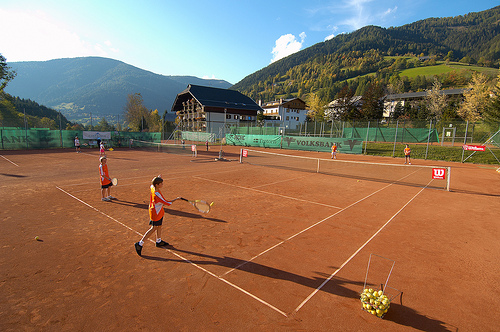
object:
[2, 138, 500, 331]
tennis court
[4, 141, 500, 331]
clay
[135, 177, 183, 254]
tenni player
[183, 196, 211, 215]
racquet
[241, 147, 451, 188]
net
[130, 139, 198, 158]
net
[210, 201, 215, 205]
tennis ball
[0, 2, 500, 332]
air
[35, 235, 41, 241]
tennis ball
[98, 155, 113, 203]
person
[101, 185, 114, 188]
black skirt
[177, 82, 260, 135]
chalet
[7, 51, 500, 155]
distance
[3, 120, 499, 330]
tennis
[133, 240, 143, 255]
shoes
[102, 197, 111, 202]
shoes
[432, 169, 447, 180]
wilson insignia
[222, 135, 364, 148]
banner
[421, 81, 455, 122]
trees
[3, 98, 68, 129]
hills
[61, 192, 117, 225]
lines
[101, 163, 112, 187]
jersey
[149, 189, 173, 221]
jersey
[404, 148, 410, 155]
jersey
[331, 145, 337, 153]
jersey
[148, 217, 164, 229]
shorts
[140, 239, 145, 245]
socks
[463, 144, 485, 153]
sign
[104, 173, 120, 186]
racquet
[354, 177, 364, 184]
tennis ball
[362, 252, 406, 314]
basket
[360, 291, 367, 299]
tennis balls